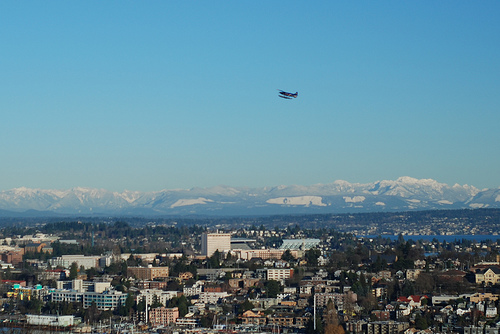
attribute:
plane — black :
[270, 82, 304, 104]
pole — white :
[311, 294, 317, 332]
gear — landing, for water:
[264, 91, 297, 108]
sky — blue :
[3, 6, 494, 172]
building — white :
[200, 228, 234, 260]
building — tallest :
[199, 227, 231, 262]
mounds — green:
[8, 276, 72, 300]